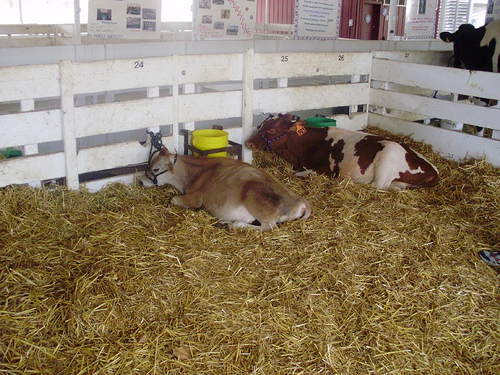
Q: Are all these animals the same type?
A: Yes, all the animals are cows.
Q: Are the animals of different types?
A: No, all the animals are cows.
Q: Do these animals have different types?
A: No, all the animals are cows.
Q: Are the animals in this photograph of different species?
A: No, all the animals are cows.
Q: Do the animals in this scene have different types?
A: No, all the animals are cows.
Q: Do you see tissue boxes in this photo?
A: No, there are no tissue boxes.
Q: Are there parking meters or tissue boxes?
A: No, there are no tissue boxes or parking meters.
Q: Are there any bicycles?
A: No, there are no bicycles.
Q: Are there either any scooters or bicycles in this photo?
A: No, there are no bicycles or scooters.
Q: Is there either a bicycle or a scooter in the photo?
A: No, there are no bicycles or scooters.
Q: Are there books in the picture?
A: No, there are no books.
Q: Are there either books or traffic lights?
A: No, there are no books or traffic lights.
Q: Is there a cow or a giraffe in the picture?
A: Yes, there is a cow.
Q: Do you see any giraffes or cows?
A: Yes, there is a cow.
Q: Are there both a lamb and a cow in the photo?
A: No, there is a cow but no lambs.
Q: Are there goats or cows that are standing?
A: Yes, the cow is standing.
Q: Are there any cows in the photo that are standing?
A: Yes, there is a cow that is standing.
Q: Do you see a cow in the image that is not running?
A: Yes, there is a cow that is standing .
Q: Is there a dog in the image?
A: No, there are no dogs.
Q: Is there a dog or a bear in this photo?
A: No, there are no dogs or bears.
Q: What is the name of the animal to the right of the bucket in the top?
A: The animal is a cow.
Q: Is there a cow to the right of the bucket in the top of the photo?
A: Yes, there is a cow to the right of the bucket.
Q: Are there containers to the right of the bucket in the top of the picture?
A: No, there is a cow to the right of the bucket.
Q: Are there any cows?
A: Yes, there is a cow.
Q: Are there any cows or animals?
A: Yes, there is a cow.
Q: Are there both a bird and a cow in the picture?
A: No, there is a cow but no birds.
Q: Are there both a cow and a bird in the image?
A: No, there is a cow but no birds.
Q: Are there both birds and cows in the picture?
A: No, there is a cow but no birds.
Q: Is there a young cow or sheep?
A: Yes, there is a young cow.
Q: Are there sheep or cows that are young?
A: Yes, the cow is young.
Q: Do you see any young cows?
A: Yes, there is a young cow.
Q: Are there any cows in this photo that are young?
A: Yes, there is a cow that is young.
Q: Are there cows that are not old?
A: Yes, there is an young cow.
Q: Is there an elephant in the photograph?
A: No, there are no elephants.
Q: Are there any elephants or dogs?
A: No, there are no elephants or dogs.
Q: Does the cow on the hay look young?
A: Yes, the cow is young.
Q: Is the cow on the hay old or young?
A: The cow is young.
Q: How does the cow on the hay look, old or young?
A: The cow is young.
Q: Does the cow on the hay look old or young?
A: The cow is young.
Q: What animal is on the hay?
A: The cow is on the hay.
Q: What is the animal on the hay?
A: The animal is a cow.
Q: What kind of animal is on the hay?
A: The animal is a cow.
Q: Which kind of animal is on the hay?
A: The animal is a cow.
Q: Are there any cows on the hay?
A: Yes, there is a cow on the hay.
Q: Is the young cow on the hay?
A: Yes, the cow is on the hay.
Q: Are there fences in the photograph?
A: Yes, there is a fence.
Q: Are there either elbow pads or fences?
A: Yes, there is a fence.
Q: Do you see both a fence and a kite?
A: No, there is a fence but no kites.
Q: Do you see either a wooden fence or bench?
A: Yes, there is a wood fence.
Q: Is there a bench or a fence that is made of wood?
A: Yes, the fence is made of wood.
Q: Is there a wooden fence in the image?
A: Yes, there is a wood fence.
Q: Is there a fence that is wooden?
A: Yes, there is a fence that is wooden.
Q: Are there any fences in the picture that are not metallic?
A: Yes, there is a wooden fence.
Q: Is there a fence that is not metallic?
A: Yes, there is a wooden fence.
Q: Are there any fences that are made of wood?
A: Yes, there is a fence that is made of wood.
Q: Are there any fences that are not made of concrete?
A: Yes, there is a fence that is made of wood.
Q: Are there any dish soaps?
A: No, there are no dish soaps.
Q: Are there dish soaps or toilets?
A: No, there are no dish soaps or toilets.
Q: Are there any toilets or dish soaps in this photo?
A: No, there are no dish soaps or toilets.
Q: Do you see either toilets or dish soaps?
A: No, there are no dish soaps or toilets.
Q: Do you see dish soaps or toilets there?
A: No, there are no dish soaps or toilets.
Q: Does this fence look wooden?
A: Yes, the fence is wooden.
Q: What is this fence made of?
A: The fence is made of wood.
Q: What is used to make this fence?
A: The fence is made of wood.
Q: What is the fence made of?
A: The fence is made of wood.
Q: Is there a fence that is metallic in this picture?
A: No, there is a fence but it is wooden.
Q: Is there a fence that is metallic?
A: No, there is a fence but it is wooden.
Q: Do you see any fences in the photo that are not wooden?
A: No, there is a fence but it is wooden.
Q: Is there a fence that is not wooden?
A: No, there is a fence but it is wooden.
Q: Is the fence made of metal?
A: No, the fence is made of wood.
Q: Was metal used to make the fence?
A: No, the fence is made of wood.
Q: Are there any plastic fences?
A: No, there is a fence but it is made of wood.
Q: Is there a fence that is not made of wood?
A: No, there is a fence but it is made of wood.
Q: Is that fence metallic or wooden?
A: The fence is wooden.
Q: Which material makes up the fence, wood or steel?
A: The fence is made of wood.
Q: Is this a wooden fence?
A: Yes, this is a wooden fence.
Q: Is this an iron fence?
A: No, this is a wooden fence.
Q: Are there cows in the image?
A: Yes, there is a cow.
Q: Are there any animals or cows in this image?
A: Yes, there is a cow.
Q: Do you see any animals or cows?
A: Yes, there is a cow.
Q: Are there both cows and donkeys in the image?
A: No, there is a cow but no donkeys.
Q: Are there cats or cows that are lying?
A: Yes, the cow is lying.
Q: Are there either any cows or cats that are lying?
A: Yes, the cow is lying.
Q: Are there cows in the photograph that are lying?
A: Yes, there is a cow that is lying.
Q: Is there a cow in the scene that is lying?
A: Yes, there is a cow that is lying.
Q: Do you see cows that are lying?
A: Yes, there is a cow that is lying.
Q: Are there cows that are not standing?
A: Yes, there is a cow that is lying.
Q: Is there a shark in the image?
A: No, there are no sharks.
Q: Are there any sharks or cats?
A: No, there are no sharks or cats.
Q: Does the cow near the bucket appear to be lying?
A: Yes, the cow is lying.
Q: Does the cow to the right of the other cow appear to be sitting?
A: No, the cow is lying.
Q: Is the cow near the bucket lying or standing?
A: The cow is lying.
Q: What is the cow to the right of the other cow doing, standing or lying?
A: The cow is lying.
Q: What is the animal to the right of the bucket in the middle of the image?
A: The animal is a cow.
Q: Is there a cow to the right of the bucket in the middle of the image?
A: Yes, there is a cow to the right of the bucket.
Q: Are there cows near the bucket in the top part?
A: Yes, there is a cow near the bucket.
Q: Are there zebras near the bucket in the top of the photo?
A: No, there is a cow near the bucket.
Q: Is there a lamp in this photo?
A: No, there are no lamps.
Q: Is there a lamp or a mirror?
A: No, there are no lamps or mirrors.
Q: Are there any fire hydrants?
A: No, there are no fire hydrants.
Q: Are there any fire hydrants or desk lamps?
A: No, there are no fire hydrants or desk lamps.